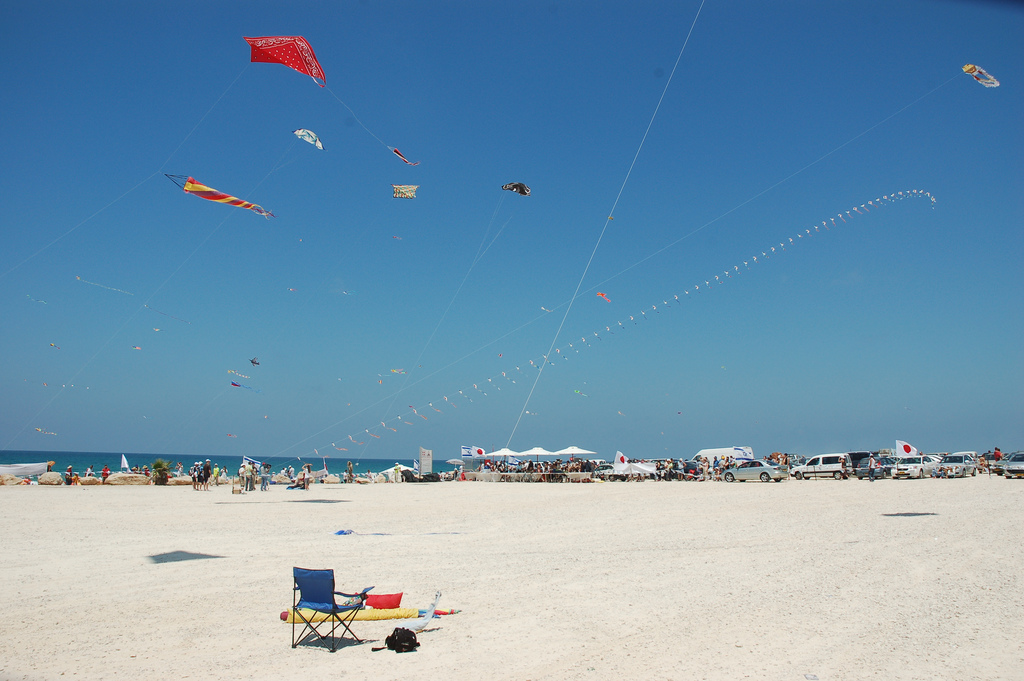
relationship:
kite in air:
[153, 152, 274, 230] [20, 22, 984, 431]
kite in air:
[287, 115, 333, 159] [20, 22, 984, 431]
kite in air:
[501, 182, 531, 198] [20, 22, 984, 431]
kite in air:
[504, 156, 546, 211] [16, 50, 950, 457]